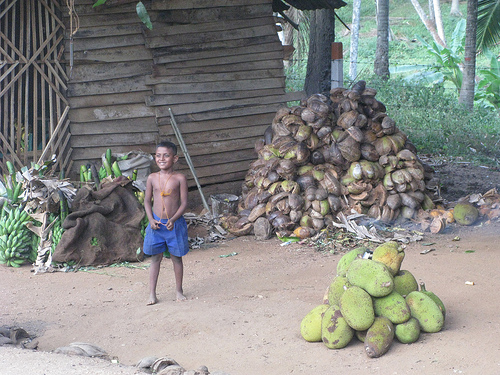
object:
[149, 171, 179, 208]
bare chest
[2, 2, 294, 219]
store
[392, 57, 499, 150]
plants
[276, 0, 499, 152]
fence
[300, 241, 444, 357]
pile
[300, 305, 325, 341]
melon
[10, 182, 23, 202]
bananas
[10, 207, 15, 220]
bananas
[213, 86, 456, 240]
destroyed fruits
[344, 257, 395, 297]
fruits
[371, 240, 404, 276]
fruits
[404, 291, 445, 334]
fruits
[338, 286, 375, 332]
fruits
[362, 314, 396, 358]
fruits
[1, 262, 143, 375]
ground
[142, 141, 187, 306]
boy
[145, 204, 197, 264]
shorts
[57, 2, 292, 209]
wood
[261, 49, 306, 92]
background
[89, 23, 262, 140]
stack